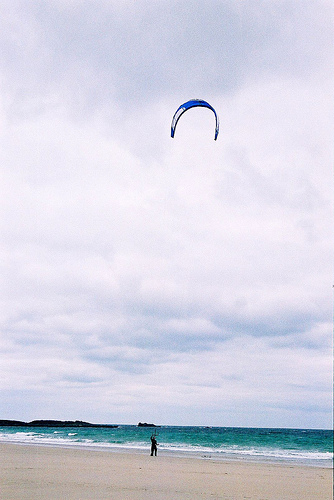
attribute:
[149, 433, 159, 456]
person — lone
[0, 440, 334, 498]
sand — clean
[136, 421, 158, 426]
rock — large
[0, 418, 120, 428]
rock — large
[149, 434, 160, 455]
person — looking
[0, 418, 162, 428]
jetty — natural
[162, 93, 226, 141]
kite — parasail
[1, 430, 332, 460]
wave — breaking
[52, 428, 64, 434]
wave — breaking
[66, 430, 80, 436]
wave — breaking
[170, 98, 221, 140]
parasail kite — blue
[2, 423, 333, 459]
water — teal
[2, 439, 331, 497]
shore — sand-covered, beach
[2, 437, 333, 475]
sand — damp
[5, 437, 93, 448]
wave — breaking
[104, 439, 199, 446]
wave — breaking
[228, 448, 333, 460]
wave — breaking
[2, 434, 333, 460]
spray — white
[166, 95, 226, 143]
kite — blue, white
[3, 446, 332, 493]
sand — brown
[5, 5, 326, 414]
sky — grey, overcast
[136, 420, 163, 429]
protrusion — large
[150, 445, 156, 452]
clothing — dark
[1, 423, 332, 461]
ocean — TURQUOISE COLORED